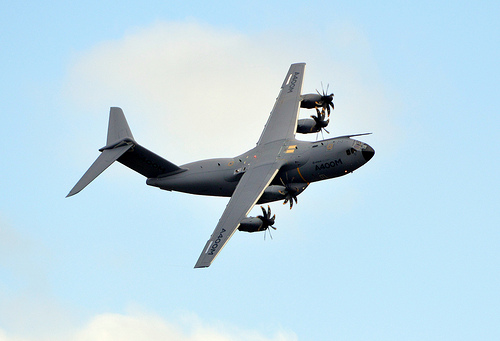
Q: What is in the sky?
A: Plane.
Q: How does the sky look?
A: Clear and blue.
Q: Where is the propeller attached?
A: On the wing.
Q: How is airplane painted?
A: Dark grey.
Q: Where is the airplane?
A: Flying in air.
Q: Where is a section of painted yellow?
A: Top of airplane.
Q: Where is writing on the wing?
A: Toward the narrow end.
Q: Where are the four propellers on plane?
A: On both wings.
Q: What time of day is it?
A: Day time.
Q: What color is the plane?
A: Black.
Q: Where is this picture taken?
A: In air.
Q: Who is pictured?
A: No one.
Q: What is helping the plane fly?
A: Propellers.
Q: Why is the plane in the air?
A: Flying.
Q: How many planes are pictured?
A: One.